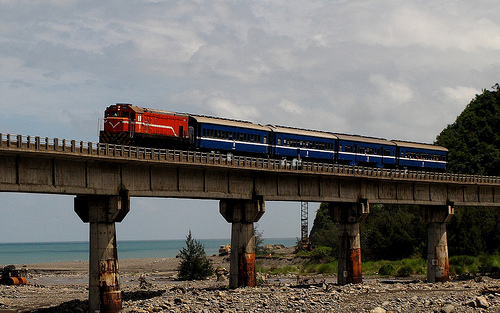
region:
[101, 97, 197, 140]
red train engine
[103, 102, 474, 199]
train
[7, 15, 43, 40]
white clouds in blue sky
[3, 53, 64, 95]
white clouds in blue sky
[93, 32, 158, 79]
white clouds in blue sky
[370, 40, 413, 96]
white clouds in blue sky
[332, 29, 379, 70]
white clouds in blue sky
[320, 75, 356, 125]
white clouds in blue sky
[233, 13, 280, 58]
white clouds in blue sky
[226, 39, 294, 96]
white clouds in blue sky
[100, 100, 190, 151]
a red train engine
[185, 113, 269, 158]
a blue train passenger car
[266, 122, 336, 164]
a blue train passenger car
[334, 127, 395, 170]
a blue train passenger car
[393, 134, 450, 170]
a blue train passenger car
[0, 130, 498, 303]
a train bridge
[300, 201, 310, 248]
a crane in distance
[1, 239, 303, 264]
a large body of water in distance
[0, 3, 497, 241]
a cloudy grey sky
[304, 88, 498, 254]
a green hillside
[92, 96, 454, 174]
Train on the bridge.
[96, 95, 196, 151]
Red train engine on the bridge.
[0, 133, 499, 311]
Bridge under the train.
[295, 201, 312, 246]
metal tower in the background.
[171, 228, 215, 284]
Tree in the background.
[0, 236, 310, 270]
Water in the background.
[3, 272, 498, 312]
Rocky landscape under the bridge.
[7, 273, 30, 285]
Rust colored barrel on the ground.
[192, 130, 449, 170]
White stripe on the train.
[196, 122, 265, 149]
Windows on the train.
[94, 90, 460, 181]
a long train passing by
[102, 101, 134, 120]
windshield of a train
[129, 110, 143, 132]
door to the train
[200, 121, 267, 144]
windows of a train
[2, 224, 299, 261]
view of the ocean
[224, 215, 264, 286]
a steel pillar supporting railroad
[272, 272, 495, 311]
a rocky platform surface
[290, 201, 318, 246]
television radio tower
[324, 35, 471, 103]
sky full of clouds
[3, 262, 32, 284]
barrels on the ground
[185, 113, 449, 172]
blue train passenger cars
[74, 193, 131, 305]
a metal post for a bridge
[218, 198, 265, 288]
a metal post for a bridge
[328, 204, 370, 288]
a metal post for a bridge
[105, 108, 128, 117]
windows on a train engine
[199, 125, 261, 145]
windows on a passenger train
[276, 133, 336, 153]
windows on a passenger train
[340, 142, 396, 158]
windows on a passenger train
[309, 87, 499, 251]
a thicket of foliage